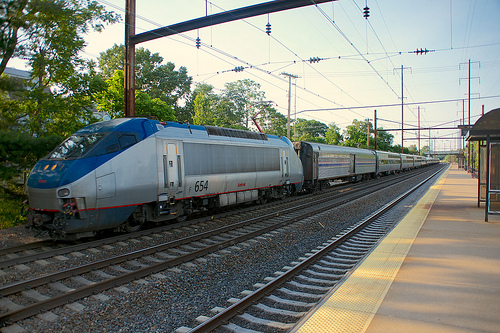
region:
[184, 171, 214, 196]
black numbers on side of train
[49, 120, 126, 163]
wind shield on front of train engine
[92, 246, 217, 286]
grey metal train tracks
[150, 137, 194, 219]
metal door on side of train engine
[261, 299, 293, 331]
train track cross ties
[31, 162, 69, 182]
orange lights on front of train engine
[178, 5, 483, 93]
metal wires hanging above train tracks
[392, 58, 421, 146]
grey metal electric pole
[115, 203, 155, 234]
black metal train wheels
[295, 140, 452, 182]
silver train cars stopped on tracks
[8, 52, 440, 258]
A train is traveling down the tracks.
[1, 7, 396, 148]
Trees growing near the train tracks.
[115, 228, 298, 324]
The gravel in between the train tracks is called track ballast.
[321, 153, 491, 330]
The platform next to the train tracks.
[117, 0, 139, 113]
The pole is made of wood.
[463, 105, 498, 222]
A weather shelter on the train platform.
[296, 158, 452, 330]
The yellow tile on the edge of the train platform.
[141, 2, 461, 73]
Power lines above the train tracks.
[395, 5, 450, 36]
The sky is blue.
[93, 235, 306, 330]
An empty part of the train tracks.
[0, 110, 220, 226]
blue and gray light rail train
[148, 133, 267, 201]
blue and gray light rail train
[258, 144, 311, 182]
blue and gray light rail train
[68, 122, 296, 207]
blue and gray light rail train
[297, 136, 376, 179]
blue and gray light rail train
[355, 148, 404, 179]
blue and gray light rail train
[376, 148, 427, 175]
blue and gray light rail train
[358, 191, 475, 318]
shadow cast on the platform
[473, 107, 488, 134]
roof on building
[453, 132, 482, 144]
overhang on the building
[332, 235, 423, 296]
yellow edge of platform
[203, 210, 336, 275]
long railroad tracks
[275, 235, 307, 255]
gravel in the middle of the tracks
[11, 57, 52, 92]
view of tall building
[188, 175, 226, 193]
black words on side of building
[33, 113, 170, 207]
sloped front of the train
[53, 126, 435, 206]
large train on the tracks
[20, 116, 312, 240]
a blue and silver train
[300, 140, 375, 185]
a silver passenger train car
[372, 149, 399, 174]
a silver passenger train car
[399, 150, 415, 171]
a silver passenger train car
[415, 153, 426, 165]
a silver passenger train car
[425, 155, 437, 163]
a silver passenger train car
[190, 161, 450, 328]
a set of train tracks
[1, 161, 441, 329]
a silver passenger train car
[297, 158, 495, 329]
a passenger boarding platform